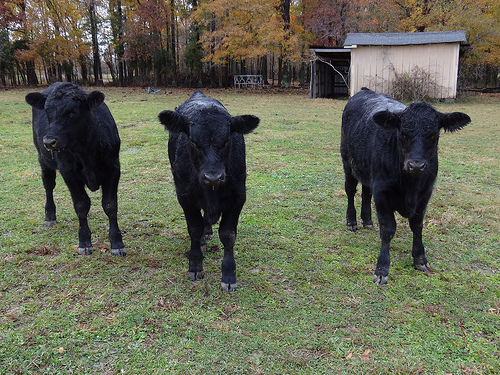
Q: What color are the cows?
A: Black.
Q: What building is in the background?
A: Shed.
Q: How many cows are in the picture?
A: 3.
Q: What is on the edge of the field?
A: Trees.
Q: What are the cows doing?
A: Standing.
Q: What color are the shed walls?
A: White.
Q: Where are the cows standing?
A: In a field.